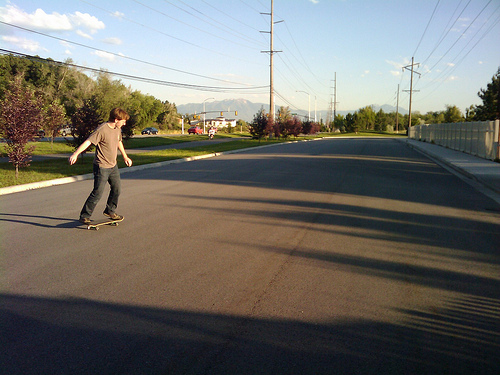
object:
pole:
[268, 0, 275, 140]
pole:
[407, 56, 414, 127]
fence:
[408, 119, 500, 163]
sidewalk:
[393, 137, 500, 205]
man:
[67, 107, 134, 225]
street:
[0, 136, 499, 375]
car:
[187, 126, 204, 135]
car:
[141, 127, 160, 135]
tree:
[0, 80, 48, 180]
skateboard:
[74, 214, 125, 231]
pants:
[77, 163, 125, 220]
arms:
[68, 130, 99, 166]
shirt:
[86, 123, 123, 170]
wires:
[0, 47, 271, 91]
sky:
[0, 0, 497, 117]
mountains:
[361, 101, 414, 116]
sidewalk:
[0, 132, 324, 165]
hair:
[108, 106, 131, 123]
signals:
[234, 110, 238, 116]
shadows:
[0, 211, 117, 231]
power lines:
[255, 0, 335, 94]